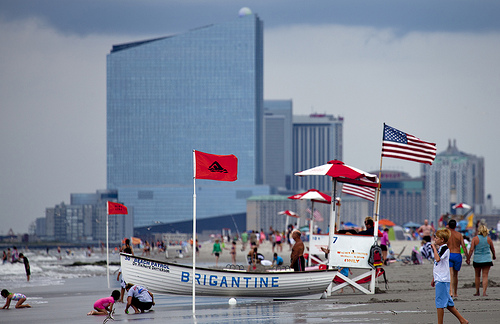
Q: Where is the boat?
A: On the sand.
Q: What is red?
A: Flag.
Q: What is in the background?
A: Buildings.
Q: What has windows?
A: The building.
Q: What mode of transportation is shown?
A: Boat.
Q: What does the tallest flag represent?
A: United States of America.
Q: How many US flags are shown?
A: 2.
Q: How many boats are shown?
A: 1.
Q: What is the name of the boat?
A: BRIGANTINE.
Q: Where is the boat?
A: Beach.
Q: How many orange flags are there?
A: 2.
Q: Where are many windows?
A: Buildings.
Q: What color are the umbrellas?
A: Red and white.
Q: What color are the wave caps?
A: White.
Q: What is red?
A: Two flags.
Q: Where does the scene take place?
A: At the beach.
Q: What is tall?
A: Buildings.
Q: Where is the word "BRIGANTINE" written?
A: On white boat.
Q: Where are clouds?
A: In the sky.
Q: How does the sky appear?
A: Overcast.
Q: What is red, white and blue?
A: American flags.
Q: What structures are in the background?
A: Tall buildings.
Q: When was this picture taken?
A: During the day.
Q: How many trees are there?
A: None.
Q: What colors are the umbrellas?
A: White and red.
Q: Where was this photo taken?
A: On the beach.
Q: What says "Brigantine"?
A: The boat.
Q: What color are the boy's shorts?
A: Blue.